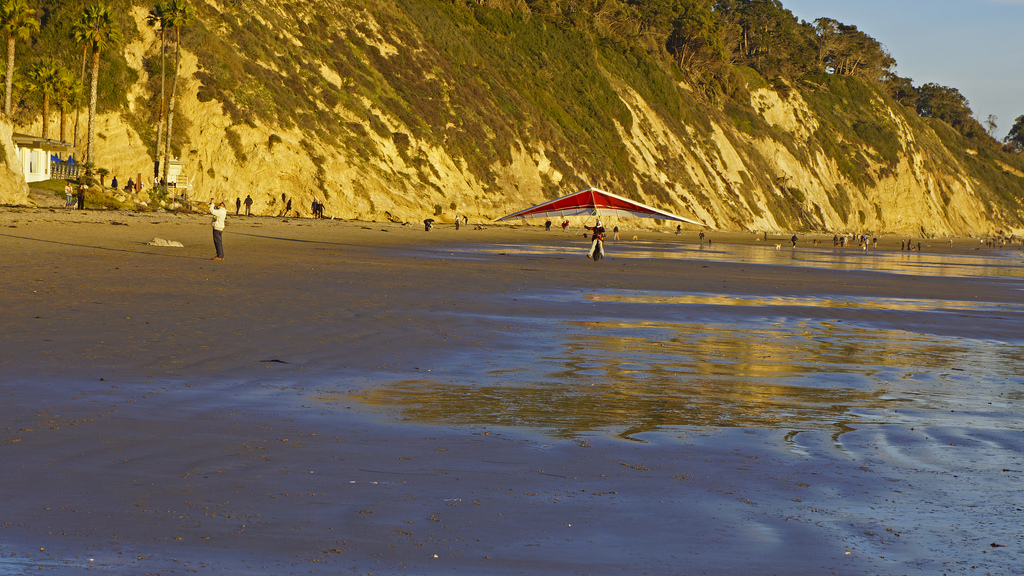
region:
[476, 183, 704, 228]
white and red kite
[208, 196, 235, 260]
person wearing white long sleeve shirt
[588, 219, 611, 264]
person holding the kite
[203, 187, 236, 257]
person standing on the sand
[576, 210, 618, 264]
person standing at the edge of the water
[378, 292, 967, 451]
reflections on the water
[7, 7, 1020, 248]
cliff behind the person with the kite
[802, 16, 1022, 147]
clear blue sky behind the cliff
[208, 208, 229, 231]
the shirt is white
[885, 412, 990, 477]
the water has small waves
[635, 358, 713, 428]
the hillside is reflecting in the water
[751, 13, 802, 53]
the trees have green leaves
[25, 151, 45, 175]
the building is white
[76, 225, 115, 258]
the sand is tan in color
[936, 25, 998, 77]
the sky is blue in color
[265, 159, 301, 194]
the hillside is yellow in color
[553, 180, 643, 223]
the wing is red and white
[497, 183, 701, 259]
a person flying a red and white kite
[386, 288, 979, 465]
reflection on the surface of wet sand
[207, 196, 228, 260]
a person is wearing a white shirt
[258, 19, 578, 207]
a sandy hillside with grass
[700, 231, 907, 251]
a group of people standing on a beach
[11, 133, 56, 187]
a building with a white exterior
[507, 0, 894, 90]
trees on a hillside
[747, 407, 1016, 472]
ripples in the surface of sand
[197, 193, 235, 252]
a person with their arm in the air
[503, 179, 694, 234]
Large red and white kite near person.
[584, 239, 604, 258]
Person is wearing khaki pants.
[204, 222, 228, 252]
Person is wearing dark pants.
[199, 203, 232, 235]
Person wearing white shirt.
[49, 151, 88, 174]
Blue umbrellas near building.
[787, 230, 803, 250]
Person wearing all dark clothing in distance.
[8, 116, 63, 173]
Small white building near blue umbrellas.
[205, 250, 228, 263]
Person wearing brown shoes.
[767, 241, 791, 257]
Tan colored dog walking on beach.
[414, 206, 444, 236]
Person on beach is bending over.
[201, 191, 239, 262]
person standing on the beach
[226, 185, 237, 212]
person standing on the beach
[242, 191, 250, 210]
person standing on the beach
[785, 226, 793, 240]
person standing on the beach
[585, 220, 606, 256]
person standing on the beach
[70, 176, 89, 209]
person standing on the beach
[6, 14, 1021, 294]
A tree lined mountain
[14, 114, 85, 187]
The small white house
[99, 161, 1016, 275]
The people on the beach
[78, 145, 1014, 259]
A crowd of people on the beach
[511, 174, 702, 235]
The red kite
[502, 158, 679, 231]
A red kite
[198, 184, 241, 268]
a person is standing up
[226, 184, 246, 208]
a person is standing up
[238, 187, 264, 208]
a person is standing up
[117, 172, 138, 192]
a person is standing up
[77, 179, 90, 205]
a person is standing up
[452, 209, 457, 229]
a person is standing up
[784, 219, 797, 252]
a person is standing up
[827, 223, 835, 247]
a person is standing up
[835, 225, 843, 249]
a person is standing up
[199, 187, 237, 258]
A person is standing up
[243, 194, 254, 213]
A person is standing up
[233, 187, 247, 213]
A person is standing up